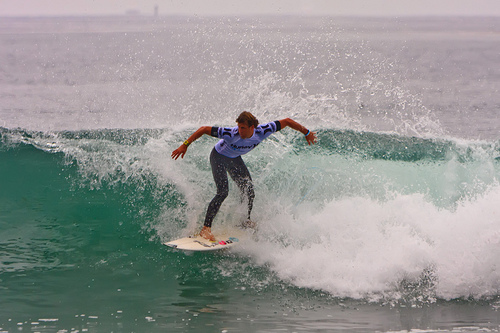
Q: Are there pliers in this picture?
A: No, there are no pliers.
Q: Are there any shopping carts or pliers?
A: No, there are no pliers or shopping carts.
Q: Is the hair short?
A: Yes, the hair is short.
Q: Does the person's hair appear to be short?
A: Yes, the hair is short.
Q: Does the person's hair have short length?
A: Yes, the hair is short.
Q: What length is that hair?
A: The hair is short.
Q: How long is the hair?
A: The hair is short.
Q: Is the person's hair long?
A: No, the hair is short.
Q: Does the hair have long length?
A: No, the hair is short.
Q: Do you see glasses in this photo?
A: No, there are no glasses.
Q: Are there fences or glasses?
A: No, there are no glasses or fences.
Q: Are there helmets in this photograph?
A: No, there are no helmets.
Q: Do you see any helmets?
A: No, there are no helmets.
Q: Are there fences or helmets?
A: No, there are no helmets or fences.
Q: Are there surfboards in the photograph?
A: Yes, there is a surfboard.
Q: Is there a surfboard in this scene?
A: Yes, there is a surfboard.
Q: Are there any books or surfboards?
A: Yes, there is a surfboard.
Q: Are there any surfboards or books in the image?
A: Yes, there is a surfboard.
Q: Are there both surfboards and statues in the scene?
A: No, there is a surfboard but no statues.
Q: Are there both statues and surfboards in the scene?
A: No, there is a surfboard but no statues.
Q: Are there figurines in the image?
A: No, there are no figurines.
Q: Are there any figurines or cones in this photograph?
A: No, there are no figurines or cones.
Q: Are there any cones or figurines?
A: No, there are no figurines or cones.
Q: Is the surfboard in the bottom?
A: Yes, the surfboard is in the bottom of the image.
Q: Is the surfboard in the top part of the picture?
A: No, the surfboard is in the bottom of the image.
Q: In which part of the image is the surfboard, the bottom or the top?
A: The surfboard is in the bottom of the image.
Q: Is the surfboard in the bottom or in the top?
A: The surfboard is in the bottom of the image.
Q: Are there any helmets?
A: No, there are no helmets.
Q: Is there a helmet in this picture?
A: No, there are no helmets.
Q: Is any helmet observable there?
A: No, there are no helmets.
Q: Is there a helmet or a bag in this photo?
A: No, there are no helmets or bags.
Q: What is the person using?
A: The person is using a surfboard.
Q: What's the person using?
A: The person is using a surfboard.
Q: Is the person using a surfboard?
A: Yes, the person is using a surfboard.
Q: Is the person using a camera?
A: No, the person is using a surfboard.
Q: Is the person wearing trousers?
A: Yes, the person is wearing trousers.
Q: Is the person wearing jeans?
A: No, the person is wearing trousers.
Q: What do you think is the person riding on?
A: The person is riding on the surfboard.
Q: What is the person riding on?
A: The person is riding on the surfboard.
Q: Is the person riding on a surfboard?
A: Yes, the person is riding on a surfboard.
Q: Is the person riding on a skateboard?
A: No, the person is riding on a surfboard.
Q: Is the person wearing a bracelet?
A: Yes, the person is wearing a bracelet.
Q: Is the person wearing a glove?
A: No, the person is wearing a bracelet.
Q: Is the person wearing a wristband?
A: Yes, the person is wearing a wristband.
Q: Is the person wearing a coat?
A: No, the person is wearing a wristband.